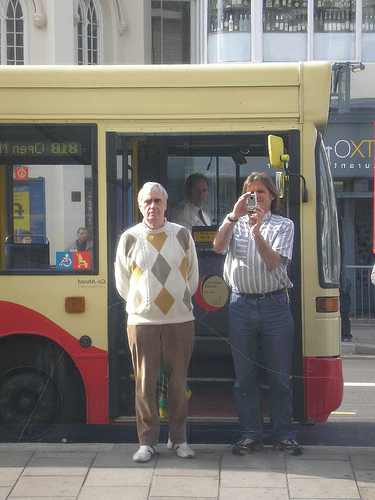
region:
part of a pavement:
[252, 453, 260, 465]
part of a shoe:
[140, 451, 154, 456]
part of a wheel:
[49, 395, 53, 412]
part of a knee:
[244, 374, 259, 380]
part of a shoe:
[137, 454, 154, 478]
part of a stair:
[225, 356, 235, 428]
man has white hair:
[131, 182, 179, 215]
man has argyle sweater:
[108, 213, 205, 337]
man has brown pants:
[123, 326, 193, 435]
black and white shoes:
[120, 431, 206, 480]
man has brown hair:
[212, 169, 293, 210]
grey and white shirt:
[205, 203, 297, 283]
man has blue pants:
[247, 284, 292, 424]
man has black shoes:
[244, 424, 302, 465]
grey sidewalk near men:
[89, 464, 297, 493]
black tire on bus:
[5, 350, 81, 451]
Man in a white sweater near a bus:
[113, 181, 199, 461]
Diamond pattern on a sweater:
[144, 229, 174, 312]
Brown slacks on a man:
[124, 317, 193, 440]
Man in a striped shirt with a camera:
[212, 171, 309, 453]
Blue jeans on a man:
[225, 285, 292, 436]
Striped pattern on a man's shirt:
[226, 258, 260, 288]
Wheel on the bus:
[0, 335, 84, 442]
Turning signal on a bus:
[312, 294, 336, 312]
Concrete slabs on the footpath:
[0, 439, 360, 496]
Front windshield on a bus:
[314, 127, 341, 288]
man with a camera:
[212, 166, 327, 466]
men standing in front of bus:
[88, 173, 316, 464]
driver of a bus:
[171, 169, 220, 227]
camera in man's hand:
[239, 184, 259, 222]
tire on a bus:
[4, 349, 76, 437]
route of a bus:
[0, 127, 87, 173]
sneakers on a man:
[235, 431, 306, 470]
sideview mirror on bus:
[256, 126, 296, 179]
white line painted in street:
[346, 374, 372, 393]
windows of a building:
[77, 4, 100, 59]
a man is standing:
[115, 179, 198, 462]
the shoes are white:
[133, 437, 194, 461]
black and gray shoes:
[233, 436, 302, 459]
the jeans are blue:
[228, 290, 293, 443]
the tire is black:
[2, 340, 81, 442]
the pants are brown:
[125, 321, 191, 445]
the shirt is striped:
[223, 208, 293, 294]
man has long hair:
[240, 172, 283, 212]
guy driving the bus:
[171, 173, 211, 232]